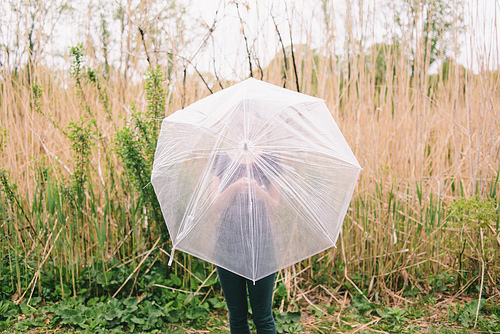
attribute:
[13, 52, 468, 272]
plants — tall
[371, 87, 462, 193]
plants — brown 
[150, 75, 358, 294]
umbrella — open, clear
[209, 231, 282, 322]
pants — black 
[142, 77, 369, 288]
umbrella — clear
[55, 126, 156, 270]
weeds — green 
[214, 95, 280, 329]
woman — white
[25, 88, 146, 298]
bushes — tall, lot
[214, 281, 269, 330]
pants — blue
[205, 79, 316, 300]
woman — arm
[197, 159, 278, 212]
shirt — purple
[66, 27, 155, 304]
plant — green, tall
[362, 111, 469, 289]
grass — long, green, yellow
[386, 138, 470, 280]
grass — yellow, green, long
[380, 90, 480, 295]
grass — long, green, yellow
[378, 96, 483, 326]
grass — yellow, green, long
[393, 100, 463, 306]
grass — long, green, yellow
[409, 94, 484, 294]
grass — yellow, green, long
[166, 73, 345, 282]
umbrella — white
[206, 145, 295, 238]
shirt — purple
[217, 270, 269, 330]
jeans — blue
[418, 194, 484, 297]
grass — tall